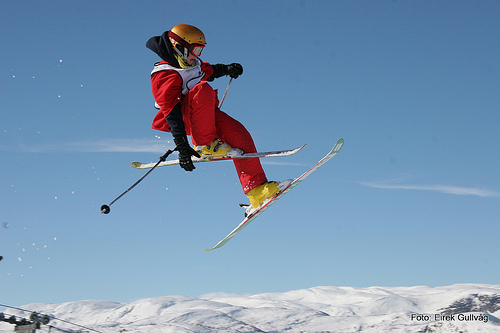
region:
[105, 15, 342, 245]
skier doing a ski trick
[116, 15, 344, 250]
a black hoody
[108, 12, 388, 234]
skier wearing black gloves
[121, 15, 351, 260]
skier floating in the air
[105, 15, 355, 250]
skier doing a ski jump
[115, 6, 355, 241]
pair of yellow shows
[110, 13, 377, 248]
a gold and yellow helmet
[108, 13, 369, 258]
two pair of ski poles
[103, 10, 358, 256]
a red jump suit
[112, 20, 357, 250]
a pair of skis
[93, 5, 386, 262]
the skier is hanging in mid air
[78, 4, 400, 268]
the skier is dressed in red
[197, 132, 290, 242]
the skier's boots are yellow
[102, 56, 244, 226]
the person has two ski poles in hand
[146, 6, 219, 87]
the helmet is gold colored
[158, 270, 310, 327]
the mountains are covered with snow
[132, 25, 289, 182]
the skier has on a black hoodie under the ski suit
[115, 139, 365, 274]
the skis are white, green & red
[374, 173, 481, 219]
the clouds are very few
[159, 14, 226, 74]
the skier looks like he's crying out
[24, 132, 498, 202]
White clouds in the sky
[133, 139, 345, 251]
A pair of skis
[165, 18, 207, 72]
Helmet on skiier's head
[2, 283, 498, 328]
Snow capped mountains in the distance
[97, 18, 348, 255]
A skiier up in the air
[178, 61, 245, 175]
A pair of black gloves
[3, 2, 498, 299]
The sky looks very blue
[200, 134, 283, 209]
A pair of yellow shoes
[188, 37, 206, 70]
Goggles over skiier's face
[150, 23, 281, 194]
Skiier wearing a red snowsuit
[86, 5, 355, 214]
a person skiing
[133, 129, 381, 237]
white skis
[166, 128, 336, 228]
yellow ski boots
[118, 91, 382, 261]
yellow ski boots on white skis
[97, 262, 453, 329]
white snow on the ground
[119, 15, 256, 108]
a person wearing a helmet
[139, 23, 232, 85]
a person wearing ski goggles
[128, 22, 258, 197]
a person wearing black gloves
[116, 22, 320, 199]
a person wearing red ski pants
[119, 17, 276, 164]
a person wearing a black sweatshirt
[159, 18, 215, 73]
a gold helmet worn by a skiier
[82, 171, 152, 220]
a pole held by a skiier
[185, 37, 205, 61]
goggles worn by a skiier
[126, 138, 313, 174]
a ski worn by a skiier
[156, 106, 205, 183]
a glove worn by a skiier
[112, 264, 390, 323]
snow-capped mountains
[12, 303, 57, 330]
a portion of a ski lift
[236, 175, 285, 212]
yellow boots worn by a skiier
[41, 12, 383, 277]
a skiier flying through the air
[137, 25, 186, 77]
a black hood at the back of a jacket